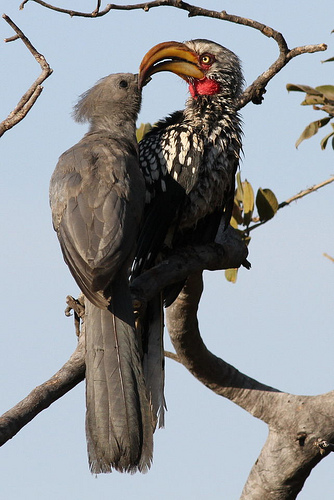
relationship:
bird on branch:
[159, 38, 251, 237] [187, 336, 314, 464]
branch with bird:
[187, 336, 314, 464] [159, 38, 251, 237]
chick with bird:
[68, 77, 141, 256] [159, 38, 251, 237]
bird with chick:
[159, 38, 251, 237] [68, 77, 141, 256]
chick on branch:
[68, 77, 141, 256] [187, 336, 314, 464]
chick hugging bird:
[68, 77, 141, 256] [159, 38, 251, 237]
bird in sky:
[159, 38, 251, 237] [38, 23, 117, 74]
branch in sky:
[187, 336, 314, 464] [38, 23, 117, 74]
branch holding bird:
[187, 336, 314, 464] [159, 38, 251, 237]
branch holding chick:
[187, 336, 314, 464] [68, 77, 141, 256]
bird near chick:
[159, 38, 251, 237] [68, 77, 141, 256]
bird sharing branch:
[159, 38, 251, 237] [187, 336, 314, 464]